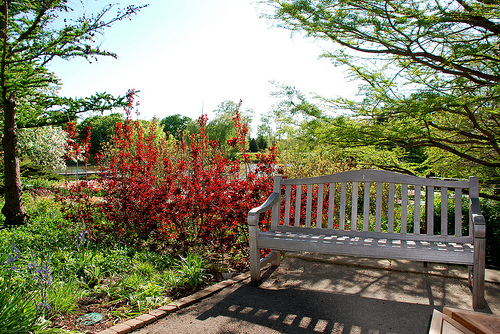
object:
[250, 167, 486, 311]
bench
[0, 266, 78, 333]
bush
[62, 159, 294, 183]
water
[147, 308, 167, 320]
bricks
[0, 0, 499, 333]
patio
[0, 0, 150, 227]
tree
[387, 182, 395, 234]
slat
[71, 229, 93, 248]
flowers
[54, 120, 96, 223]
plant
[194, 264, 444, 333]
shadow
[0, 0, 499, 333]
setting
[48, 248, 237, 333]
dirt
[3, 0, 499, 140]
sky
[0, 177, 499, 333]
ground